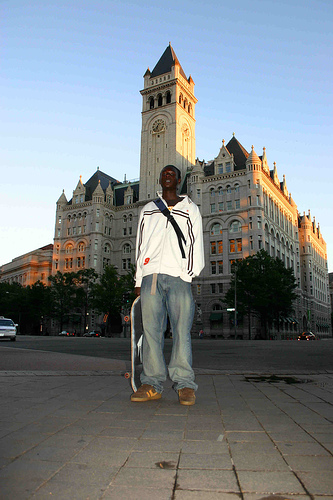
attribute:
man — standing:
[124, 160, 216, 402]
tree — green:
[225, 247, 309, 342]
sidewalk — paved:
[24, 396, 302, 497]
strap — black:
[149, 195, 189, 261]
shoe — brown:
[170, 384, 200, 410]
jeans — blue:
[131, 271, 204, 396]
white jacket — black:
[137, 193, 207, 280]